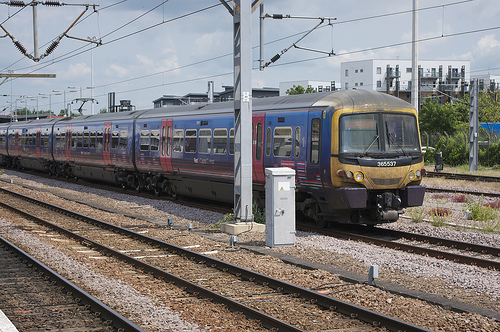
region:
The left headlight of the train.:
[356, 174, 362, 181]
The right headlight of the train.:
[416, 168, 422, 175]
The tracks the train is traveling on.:
[346, 221, 498, 261]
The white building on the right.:
[341, 56, 471, 99]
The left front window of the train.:
[343, 114, 380, 157]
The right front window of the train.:
[381, 115, 415, 157]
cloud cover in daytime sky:
[1, 0, 497, 112]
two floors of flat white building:
[339, 60, 471, 92]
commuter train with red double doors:
[0, 89, 425, 227]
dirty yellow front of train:
[330, 106, 427, 222]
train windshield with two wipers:
[338, 112, 420, 161]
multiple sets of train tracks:
[1, 166, 498, 330]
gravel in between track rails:
[0, 164, 497, 329]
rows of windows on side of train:
[0, 126, 303, 156]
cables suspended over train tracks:
[0, 0, 497, 327]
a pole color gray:
[224, 0, 264, 238]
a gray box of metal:
[256, 160, 371, 259]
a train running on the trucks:
[3, 85, 488, 250]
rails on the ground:
[4, 185, 496, 328]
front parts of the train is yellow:
[317, 93, 434, 224]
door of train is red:
[153, 110, 178, 174]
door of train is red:
[96, 117, 116, 171]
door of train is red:
[60, 122, 75, 165]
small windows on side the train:
[170, 123, 237, 141]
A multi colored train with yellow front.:
[0, 89, 427, 226]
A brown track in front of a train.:
[335, 219, 498, 268]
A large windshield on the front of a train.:
[339, 112, 419, 155]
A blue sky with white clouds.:
[0, 1, 498, 113]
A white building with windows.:
[341, 59, 471, 97]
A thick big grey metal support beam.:
[230, 2, 252, 219]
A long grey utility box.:
[263, 166, 295, 245]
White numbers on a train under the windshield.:
[375, 161, 396, 166]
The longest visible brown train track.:
[1, 186, 431, 331]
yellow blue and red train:
[1, 82, 434, 224]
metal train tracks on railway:
[2, 161, 497, 326]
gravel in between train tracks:
[6, 162, 471, 325]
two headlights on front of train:
[352, 161, 427, 182]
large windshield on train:
[337, 113, 419, 153]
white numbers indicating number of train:
[373, 158, 400, 168]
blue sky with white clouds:
[15, 0, 495, 108]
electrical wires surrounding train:
[5, 2, 496, 142]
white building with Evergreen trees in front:
[340, 50, 470, 82]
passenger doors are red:
[156, 118, 176, 170]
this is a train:
[19, 85, 414, 227]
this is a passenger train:
[17, 82, 427, 223]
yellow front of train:
[306, 85, 441, 200]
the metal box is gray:
[265, 165, 295, 245]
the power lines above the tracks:
[0, 0, 499, 330]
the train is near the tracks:
[0, 87, 499, 330]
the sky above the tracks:
[0, 0, 498, 330]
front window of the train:
[340, 114, 419, 157]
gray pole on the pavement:
[229, 3, 256, 223]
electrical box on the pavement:
[266, 166, 298, 243]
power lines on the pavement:
[10, 5, 100, 61]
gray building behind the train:
[341, 63, 409, 84]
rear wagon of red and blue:
[4, 123, 55, 154]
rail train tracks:
[409, 230, 469, 257]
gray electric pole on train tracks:
[464, 82, 479, 170]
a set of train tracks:
[0, 237, 142, 330]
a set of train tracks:
[1, 186, 423, 330]